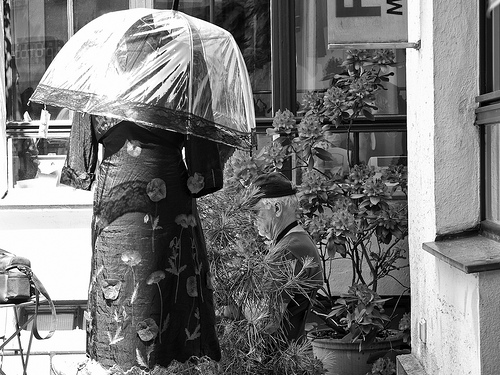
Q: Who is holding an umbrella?
A: The woman.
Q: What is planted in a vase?
A: A plant.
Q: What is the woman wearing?
A: A dress.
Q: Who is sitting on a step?
A: The man.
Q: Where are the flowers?
A: On the plant.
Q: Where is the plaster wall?
A: On the building.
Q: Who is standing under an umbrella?
A: A lady.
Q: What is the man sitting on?
A: A bench.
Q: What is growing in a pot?
A: A plant.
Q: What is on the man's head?
A: A cap.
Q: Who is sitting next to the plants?
A: A man.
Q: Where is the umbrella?
A: On top of the mannequin.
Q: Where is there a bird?
A: On the dress.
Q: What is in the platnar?
A: A plant.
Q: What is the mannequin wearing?
A: A dress.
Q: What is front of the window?
A: A mannequin.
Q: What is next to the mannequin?
A: A plant.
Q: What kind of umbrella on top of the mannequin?
A: Domed shaped umbrella.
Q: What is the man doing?
A: Sitting.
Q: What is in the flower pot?
A: A plant is in the flower pot.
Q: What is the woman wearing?
A: A dark dress with a floral motif.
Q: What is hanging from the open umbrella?
A: A tag is hanging from the open umbrella.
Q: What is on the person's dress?
A: Flowers is on the person's dress.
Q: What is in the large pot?
A: Flowers is in the large pot.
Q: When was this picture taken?
A: Daytime.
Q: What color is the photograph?
A: Black and white.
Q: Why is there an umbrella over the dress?
A: For protection.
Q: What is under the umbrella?
A: A dress.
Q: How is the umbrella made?
A: Of plastic.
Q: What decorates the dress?
A: Flowers.